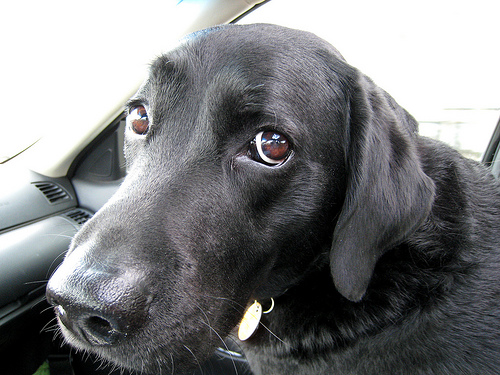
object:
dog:
[46, 22, 499, 374]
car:
[2, 0, 499, 374]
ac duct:
[27, 179, 75, 206]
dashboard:
[0, 163, 81, 233]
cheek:
[152, 280, 298, 375]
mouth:
[51, 293, 255, 373]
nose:
[45, 266, 152, 349]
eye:
[235, 124, 297, 168]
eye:
[123, 103, 152, 138]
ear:
[328, 74, 437, 302]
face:
[50, 56, 323, 368]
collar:
[236, 250, 330, 342]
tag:
[238, 298, 263, 342]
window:
[232, 0, 499, 169]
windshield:
[0, 0, 200, 166]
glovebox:
[0, 206, 104, 327]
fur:
[46, 23, 499, 374]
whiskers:
[36, 233, 74, 244]